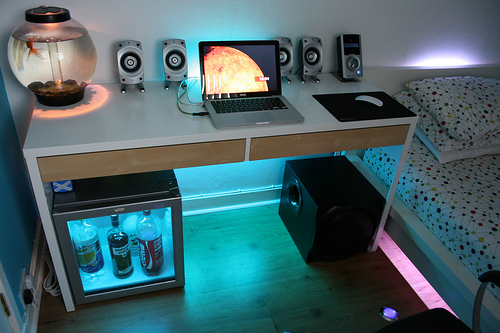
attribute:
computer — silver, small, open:
[199, 41, 307, 129]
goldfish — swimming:
[22, 37, 45, 60]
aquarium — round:
[6, 6, 98, 107]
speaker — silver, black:
[297, 35, 325, 84]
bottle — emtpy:
[136, 209, 164, 277]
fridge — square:
[53, 171, 184, 307]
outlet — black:
[20, 288, 33, 308]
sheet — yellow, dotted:
[368, 145, 500, 261]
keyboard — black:
[211, 98, 287, 115]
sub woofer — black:
[277, 155, 385, 264]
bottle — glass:
[107, 212, 134, 280]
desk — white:
[22, 70, 422, 314]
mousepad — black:
[311, 90, 417, 122]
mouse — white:
[353, 89, 384, 108]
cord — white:
[41, 250, 59, 296]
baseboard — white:
[184, 185, 281, 215]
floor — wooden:
[187, 238, 413, 333]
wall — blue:
[0, 77, 41, 315]